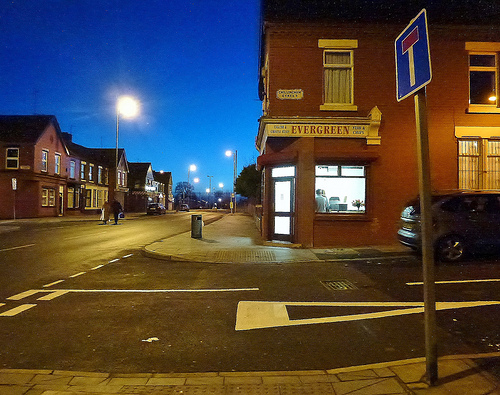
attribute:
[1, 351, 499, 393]
sidewalk — gray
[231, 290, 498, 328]
lines — white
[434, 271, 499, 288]
lines — white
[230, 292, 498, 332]
lines — white, triangular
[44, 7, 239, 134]
sky — dark, clear, blue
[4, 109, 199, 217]
houses — connected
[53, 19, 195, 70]
sky — clear, dark, blue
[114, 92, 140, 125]
lamp — on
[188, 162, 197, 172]
lamp — on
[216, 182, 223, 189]
lamp — on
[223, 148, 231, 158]
lamp — on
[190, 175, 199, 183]
lamp — on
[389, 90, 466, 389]
pole — gray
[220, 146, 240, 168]
lamp — on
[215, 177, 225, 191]
lamp — on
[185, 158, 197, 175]
lamp — on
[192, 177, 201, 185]
lamp — on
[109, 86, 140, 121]
lamp — on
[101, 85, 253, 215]
street light — silver, white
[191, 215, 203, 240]
garbage can — gray, brown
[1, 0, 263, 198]
blue sky — dark, clear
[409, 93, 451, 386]
pole — gray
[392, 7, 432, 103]
sign — blue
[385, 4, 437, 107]
sign — blue, white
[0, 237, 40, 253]
lines — yellow